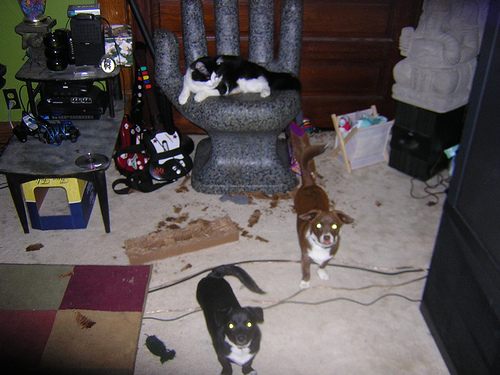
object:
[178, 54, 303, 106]
cat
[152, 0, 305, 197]
hand chair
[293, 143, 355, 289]
dog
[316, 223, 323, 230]
glowing eyes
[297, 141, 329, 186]
tail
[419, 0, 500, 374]
television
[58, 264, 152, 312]
rug square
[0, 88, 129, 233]
table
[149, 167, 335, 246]
destroyed area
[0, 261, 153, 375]
rug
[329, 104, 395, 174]
container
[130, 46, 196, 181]
guitar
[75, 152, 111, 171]
disc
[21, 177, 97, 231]
box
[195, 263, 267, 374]
dogs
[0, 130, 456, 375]
floor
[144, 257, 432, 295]
wires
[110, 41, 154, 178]
guitars